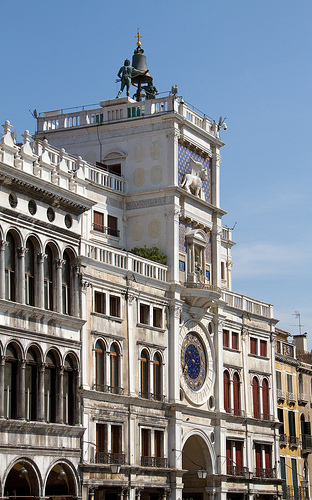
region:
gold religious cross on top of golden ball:
[128, 19, 144, 44]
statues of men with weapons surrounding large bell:
[97, 44, 168, 95]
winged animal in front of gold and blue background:
[167, 116, 216, 206]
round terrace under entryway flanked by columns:
[175, 212, 225, 309]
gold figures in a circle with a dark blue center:
[165, 305, 223, 407]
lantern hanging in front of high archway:
[175, 425, 212, 493]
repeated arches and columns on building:
[0, 333, 85, 438]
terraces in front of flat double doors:
[83, 410, 172, 467]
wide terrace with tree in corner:
[81, 196, 169, 277]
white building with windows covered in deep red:
[216, 302, 278, 491]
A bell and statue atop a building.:
[110, 23, 158, 103]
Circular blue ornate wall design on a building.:
[177, 314, 217, 410]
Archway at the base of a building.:
[181, 434, 219, 499]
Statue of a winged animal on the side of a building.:
[176, 137, 213, 206]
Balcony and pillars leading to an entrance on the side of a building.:
[178, 213, 221, 300]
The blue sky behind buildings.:
[239, 1, 309, 298]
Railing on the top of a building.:
[0, 118, 124, 185]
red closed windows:
[93, 209, 116, 233]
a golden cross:
[133, 25, 140, 46]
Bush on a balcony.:
[124, 246, 168, 265]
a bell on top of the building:
[129, 46, 149, 83]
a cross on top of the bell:
[130, 24, 147, 46]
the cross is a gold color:
[129, 25, 145, 50]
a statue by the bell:
[112, 57, 141, 94]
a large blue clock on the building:
[183, 332, 206, 390]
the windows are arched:
[2, 337, 79, 422]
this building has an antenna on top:
[276, 303, 311, 498]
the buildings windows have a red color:
[223, 329, 272, 482]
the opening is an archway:
[184, 428, 214, 498]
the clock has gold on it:
[184, 361, 204, 387]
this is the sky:
[184, 23, 274, 83]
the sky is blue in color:
[259, 109, 295, 166]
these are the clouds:
[242, 249, 283, 265]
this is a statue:
[119, 59, 134, 90]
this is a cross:
[136, 30, 144, 43]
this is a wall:
[133, 146, 165, 178]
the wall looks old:
[138, 152, 164, 186]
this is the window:
[93, 349, 104, 381]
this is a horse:
[185, 170, 206, 193]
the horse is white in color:
[186, 172, 196, 180]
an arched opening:
[168, 422, 223, 499]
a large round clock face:
[167, 317, 225, 401]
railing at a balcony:
[91, 447, 129, 467]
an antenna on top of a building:
[289, 308, 305, 335]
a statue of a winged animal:
[176, 157, 210, 195]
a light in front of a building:
[196, 465, 209, 480]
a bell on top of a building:
[128, 45, 155, 89]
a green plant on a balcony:
[122, 243, 170, 272]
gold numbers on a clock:
[180, 333, 212, 395]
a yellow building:
[267, 325, 309, 499]